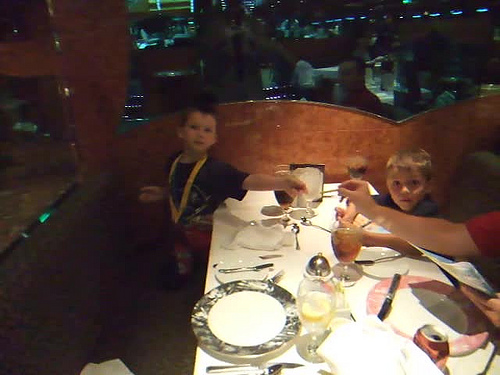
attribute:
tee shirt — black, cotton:
[153, 150, 240, 218]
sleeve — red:
[468, 210, 498, 260]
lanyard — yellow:
[163, 161, 201, 217]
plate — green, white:
[187, 278, 299, 359]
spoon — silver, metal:
[303, 210, 333, 234]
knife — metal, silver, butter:
[375, 270, 407, 318]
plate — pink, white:
[370, 270, 488, 351]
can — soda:
[414, 317, 452, 371]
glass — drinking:
[327, 224, 364, 284]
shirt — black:
[160, 152, 245, 225]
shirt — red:
[341, 88, 392, 111]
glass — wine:
[294, 278, 333, 360]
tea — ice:
[332, 237, 357, 262]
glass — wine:
[330, 223, 359, 291]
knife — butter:
[213, 260, 274, 276]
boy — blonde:
[363, 132, 444, 244]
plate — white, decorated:
[180, 264, 309, 364]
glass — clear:
[183, 260, 307, 365]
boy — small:
[154, 86, 269, 267]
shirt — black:
[140, 142, 240, 235]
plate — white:
[203, 225, 288, 296]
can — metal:
[400, 304, 461, 373]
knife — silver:
[364, 266, 406, 333]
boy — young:
[358, 116, 457, 259]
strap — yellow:
[158, 139, 213, 220]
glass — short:
[325, 220, 378, 277]